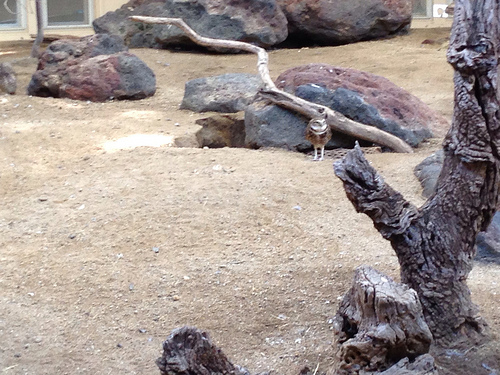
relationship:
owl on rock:
[294, 113, 338, 164] [80, 40, 148, 106]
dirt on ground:
[64, 110, 155, 225] [158, 181, 342, 270]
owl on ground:
[294, 113, 338, 164] [158, 181, 342, 270]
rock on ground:
[80, 40, 148, 106] [158, 181, 342, 270]